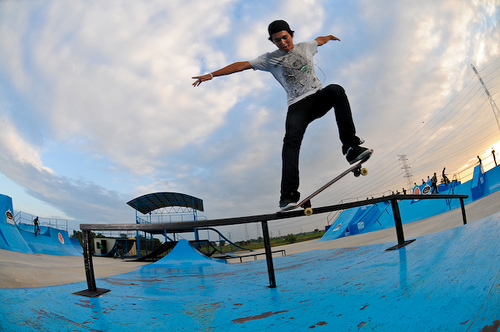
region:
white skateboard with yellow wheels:
[287, 149, 369, 214]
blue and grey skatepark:
[0, 141, 499, 330]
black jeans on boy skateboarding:
[276, 80, 362, 200]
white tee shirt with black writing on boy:
[252, 35, 322, 103]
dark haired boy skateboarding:
[189, 11, 366, 201]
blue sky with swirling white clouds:
[1, 0, 498, 241]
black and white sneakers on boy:
[279, 140, 374, 212]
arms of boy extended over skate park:
[186, 31, 353, 93]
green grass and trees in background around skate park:
[150, 226, 328, 255]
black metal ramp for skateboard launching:
[69, 179, 481, 300]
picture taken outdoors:
[6, 6, 473, 329]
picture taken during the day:
[15, 18, 499, 313]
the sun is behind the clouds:
[3, 0, 493, 323]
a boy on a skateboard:
[172, 22, 377, 179]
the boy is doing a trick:
[175, 30, 397, 181]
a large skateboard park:
[10, 200, 490, 327]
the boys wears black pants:
[262, 100, 419, 152]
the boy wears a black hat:
[260, 17, 281, 37]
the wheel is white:
[291, 192, 316, 212]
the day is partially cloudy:
[19, 23, 166, 173]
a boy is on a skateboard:
[4, 2, 494, 324]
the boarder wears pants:
[285, 122, 365, 156]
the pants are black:
[300, 108, 360, 185]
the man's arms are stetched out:
[165, 40, 353, 75]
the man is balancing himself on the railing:
[167, 15, 402, 207]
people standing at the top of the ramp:
[404, 170, 471, 192]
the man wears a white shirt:
[267, 56, 319, 86]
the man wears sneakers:
[275, 143, 405, 174]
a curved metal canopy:
[127, 191, 204, 216]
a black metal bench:
[76, 190, 467, 298]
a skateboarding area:
[1, 160, 498, 328]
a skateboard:
[269, 157, 370, 216]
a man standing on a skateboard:
[190, 18, 373, 213]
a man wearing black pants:
[271, 85, 366, 207]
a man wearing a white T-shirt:
[246, 40, 323, 104]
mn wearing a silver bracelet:
[208, 68, 215, 79]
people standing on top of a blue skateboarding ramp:
[357, 163, 451, 200]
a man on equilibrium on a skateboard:
[190, 18, 375, 216]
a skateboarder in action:
[182, 11, 379, 221]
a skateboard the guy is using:
[270, 143, 381, 215]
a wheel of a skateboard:
[303, 205, 314, 217]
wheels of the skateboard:
[351, 164, 372, 179]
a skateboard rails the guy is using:
[64, 185, 481, 300]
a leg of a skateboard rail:
[73, 230, 111, 302]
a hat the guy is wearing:
[265, 17, 297, 37]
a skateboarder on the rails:
[186, 17, 379, 217]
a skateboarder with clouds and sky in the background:
[177, 12, 382, 223]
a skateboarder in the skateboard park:
[4, 11, 489, 324]